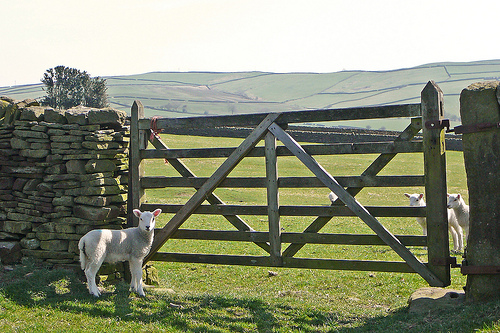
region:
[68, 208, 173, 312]
white lamb standing outside fence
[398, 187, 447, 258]
white lamb standing inside gate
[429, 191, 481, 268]
white lamb standing inside gate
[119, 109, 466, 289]
wooden farm gate to pasture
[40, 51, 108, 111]
tree with leaves from a distance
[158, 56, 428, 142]
hillside at a distance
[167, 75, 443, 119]
farming crop plots from a distance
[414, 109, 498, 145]
metal attaching gate to stone wall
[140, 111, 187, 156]
strip of red cloth tied to top of gate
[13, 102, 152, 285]
stone way going in to pasture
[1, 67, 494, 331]
Image of a farm scene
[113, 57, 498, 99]
Green hills in the distance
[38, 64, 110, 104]
Top of a tree with leaves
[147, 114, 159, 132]
A rope tied around the gate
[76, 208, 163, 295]
A goat standing outside the gate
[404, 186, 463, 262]
two goats inside the gate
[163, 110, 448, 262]
A large gate made of wood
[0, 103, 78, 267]
A wall made of stones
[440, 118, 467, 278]
Hinges on the gate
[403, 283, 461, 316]
A rock under the gate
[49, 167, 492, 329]
the lamb are white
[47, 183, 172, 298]
lamb standing in front of gate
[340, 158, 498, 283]
lamb standing behind gate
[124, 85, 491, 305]
the gate is made of wood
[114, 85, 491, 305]
the gate is brown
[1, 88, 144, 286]
wall made of stone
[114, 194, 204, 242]
inside of lamb's ears are pink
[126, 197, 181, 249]
lamb looking at camera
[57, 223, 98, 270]
lamb's tail is white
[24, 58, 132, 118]
trees behind the stone wall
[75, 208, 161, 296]
sheep standing in front of the fence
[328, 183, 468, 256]
sheep standing behind the fence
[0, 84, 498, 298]
a stone fence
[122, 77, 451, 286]
a wooden gate in the fence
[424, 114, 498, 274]
metal joints of the gate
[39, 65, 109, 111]
a tree in the field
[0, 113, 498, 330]
a large, grassy field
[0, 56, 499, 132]
a green hill behind the field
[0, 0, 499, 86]
a bright daytime sky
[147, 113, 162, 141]
a red string tied to the gate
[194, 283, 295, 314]
green grass and brown dirt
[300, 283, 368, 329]
green grass and brown dirt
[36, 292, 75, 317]
green grass and brown dirt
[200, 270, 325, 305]
green grass and brown dirt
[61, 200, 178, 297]
white lamb near fence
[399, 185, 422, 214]
white lamb near fence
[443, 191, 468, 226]
white lamb near fence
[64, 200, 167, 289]
white sheep near fence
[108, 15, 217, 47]
white clouds against blue sky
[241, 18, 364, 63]
white clouds against blue sky